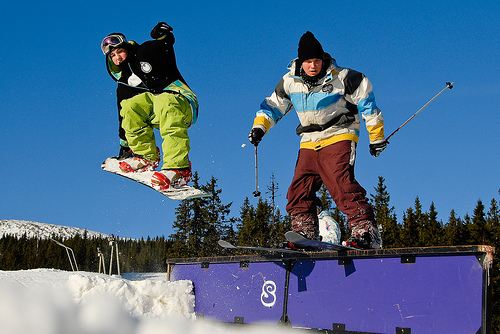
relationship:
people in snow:
[99, 22, 385, 254] [2, 268, 235, 333]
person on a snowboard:
[99, 22, 198, 191] [102, 159, 211, 203]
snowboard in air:
[102, 159, 211, 203] [3, 3, 497, 334]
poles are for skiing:
[384, 80, 452, 141] [216, 230, 363, 253]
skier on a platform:
[251, 32, 386, 250] [164, 244, 494, 332]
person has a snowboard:
[99, 22, 198, 191] [102, 159, 211, 203]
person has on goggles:
[99, 22, 198, 191] [101, 33, 123, 51]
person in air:
[99, 22, 198, 191] [3, 3, 497, 334]